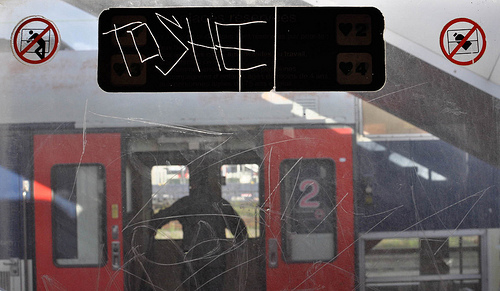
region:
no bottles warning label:
[440, 17, 486, 65]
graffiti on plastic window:
[93, 6, 283, 87]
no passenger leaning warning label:
[9, 12, 62, 64]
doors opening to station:
[26, 115, 361, 285]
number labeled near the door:
[291, 175, 323, 217]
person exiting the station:
[149, 171, 252, 288]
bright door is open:
[31, 126, 125, 289]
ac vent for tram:
[284, 94, 319, 121]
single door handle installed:
[266, 235, 278, 270]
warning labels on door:
[111, 200, 117, 220]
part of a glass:
[257, 172, 330, 250]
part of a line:
[256, 185, 272, 216]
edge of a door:
[249, 160, 274, 206]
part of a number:
[294, 165, 320, 217]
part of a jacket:
[195, 217, 225, 250]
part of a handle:
[262, 235, 277, 267]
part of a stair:
[386, 148, 418, 176]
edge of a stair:
[386, 155, 421, 180]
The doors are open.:
[35, 128, 363, 288]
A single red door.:
[36, 132, 124, 289]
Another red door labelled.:
[260, 126, 358, 290]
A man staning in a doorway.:
[141, 156, 260, 290]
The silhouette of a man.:
[150, 172, 249, 289]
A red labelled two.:
[297, 173, 323, 211]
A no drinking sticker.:
[436, 11, 493, 73]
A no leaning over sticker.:
[6, 13, 66, 72]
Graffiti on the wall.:
[108, 13, 278, 89]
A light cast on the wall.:
[1, 166, 33, 211]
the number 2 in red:
[275, 158, 342, 245]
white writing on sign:
[70, 1, 275, 118]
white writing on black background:
[91, 6, 271, 121]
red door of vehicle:
[257, 116, 358, 256]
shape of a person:
[156, 168, 250, 256]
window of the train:
[350, 130, 438, 245]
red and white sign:
[418, 11, 488, 95]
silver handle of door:
[256, 231, 289, 283]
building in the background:
[153, 168, 188, 200]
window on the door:
[44, 152, 109, 286]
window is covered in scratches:
[69, 95, 432, 260]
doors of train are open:
[67, 125, 354, 267]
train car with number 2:
[296, 164, 325, 214]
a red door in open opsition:
[259, 113, 375, 285]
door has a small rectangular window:
[258, 140, 358, 272]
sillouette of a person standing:
[167, 159, 253, 261]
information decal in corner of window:
[11, 12, 68, 71]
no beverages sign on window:
[429, 17, 494, 74]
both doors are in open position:
[42, 117, 375, 289]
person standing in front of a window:
[160, 173, 249, 253]